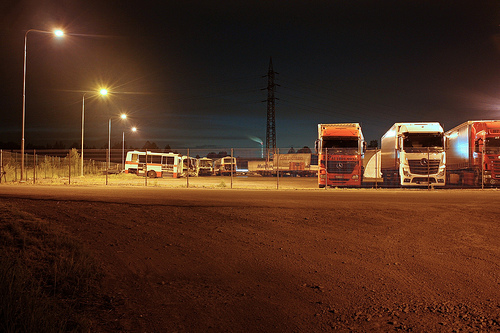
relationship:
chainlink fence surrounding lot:
[1, 147, 497, 188] [0, 0, 499, 330]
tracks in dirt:
[347, 289, 485, 331] [5, 187, 497, 332]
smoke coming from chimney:
[240, 123, 290, 155] [264, 50, 276, 162]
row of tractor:
[315, 115, 499, 192] [309, 119, 365, 192]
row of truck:
[315, 115, 499, 192] [376, 120, 450, 192]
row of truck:
[315, 115, 499, 192] [448, 117, 498, 181]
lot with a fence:
[29, 98, 496, 275] [15, 136, 498, 198]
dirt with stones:
[0, 187, 500, 333] [208, 180, 433, 305]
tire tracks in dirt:
[319, 196, 445, 296] [5, 187, 497, 332]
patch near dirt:
[3, 232, 110, 331] [12, 195, 494, 318]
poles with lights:
[18, 25, 38, 180] [47, 19, 72, 39]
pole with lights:
[78, 90, 88, 177] [91, 79, 111, 96]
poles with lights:
[106, 106, 114, 174] [116, 108, 128, 119]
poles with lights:
[106, 106, 114, 174] [128, 121, 136, 132]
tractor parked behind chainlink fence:
[310, 117, 364, 184] [1, 147, 496, 189]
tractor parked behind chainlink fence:
[380, 112, 446, 192] [1, 147, 496, 189]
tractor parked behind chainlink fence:
[444, 117, 497, 185] [1, 147, 496, 189]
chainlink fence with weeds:
[1, 147, 496, 189] [17, 144, 83, 179]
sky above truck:
[3, 3, 498, 155] [317, 122, 365, 185]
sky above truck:
[3, 3, 498, 155] [380, 120, 447, 185]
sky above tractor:
[3, 3, 498, 155] [444, 117, 498, 189]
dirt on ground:
[5, 187, 497, 332] [75, 231, 156, 290]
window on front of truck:
[400, 130, 444, 152] [377, 114, 451, 189]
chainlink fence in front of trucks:
[1, 147, 496, 189] [317, 122, 360, 185]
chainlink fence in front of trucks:
[1, 147, 496, 189] [380, 121, 445, 186]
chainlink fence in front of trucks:
[1, 147, 496, 189] [445, 118, 490, 188]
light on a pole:
[96, 85, 111, 97] [78, 90, 96, 173]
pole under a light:
[78, 90, 88, 177] [94, 82, 109, 98]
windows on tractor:
[136, 151, 178, 166] [309, 119, 365, 192]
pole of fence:
[2, 149, 499, 194] [1, 148, 493, 188]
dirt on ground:
[0, 187, 500, 333] [255, 236, 379, 276]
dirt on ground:
[0, 187, 500, 333] [6, 163, 493, 329]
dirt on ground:
[5, 187, 497, 332] [0, 178, 496, 330]